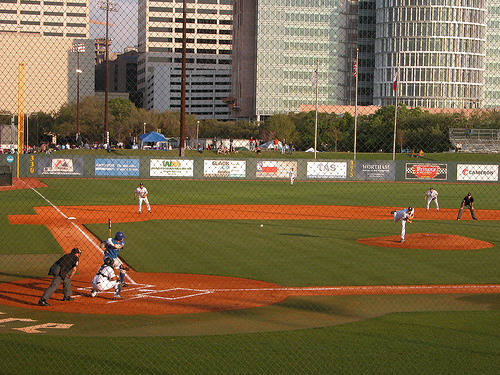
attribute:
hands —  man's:
[456, 202, 477, 209]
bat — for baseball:
[99, 217, 118, 247]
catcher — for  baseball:
[88, 257, 131, 302]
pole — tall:
[333, 44, 384, 171]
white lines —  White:
[73, 279, 213, 305]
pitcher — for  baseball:
[385, 195, 420, 245]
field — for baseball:
[0, 14, 467, 373]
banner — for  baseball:
[148, 158, 195, 177]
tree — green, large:
[260, 113, 298, 145]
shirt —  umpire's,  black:
[55, 254, 79, 264]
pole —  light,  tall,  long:
[66, 31, 91, 106]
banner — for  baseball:
[28, 155, 85, 177]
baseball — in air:
[215, 187, 295, 240]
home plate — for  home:
[140, 285, 155, 292]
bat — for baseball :
[86, 212, 119, 232]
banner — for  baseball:
[146, 161, 206, 184]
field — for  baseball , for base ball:
[5, 181, 497, 372]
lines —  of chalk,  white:
[129, 274, 347, 301]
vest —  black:
[46, 253, 79, 280]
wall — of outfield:
[18, 155, 498, 181]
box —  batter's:
[71, 274, 153, 293]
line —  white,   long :
[213, 283, 497, 292]